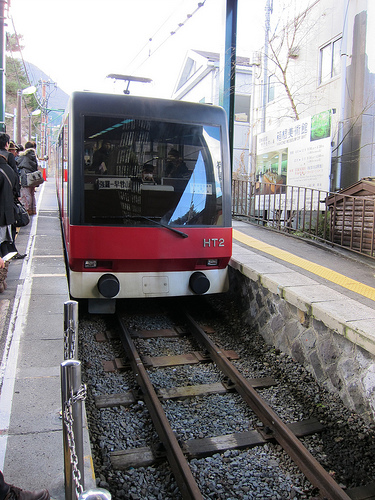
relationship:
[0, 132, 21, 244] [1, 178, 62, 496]
people standing on platform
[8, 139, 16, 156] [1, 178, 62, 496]
person standing on platform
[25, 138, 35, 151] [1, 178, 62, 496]
person standing on platform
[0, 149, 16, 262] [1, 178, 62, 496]
man standing on platform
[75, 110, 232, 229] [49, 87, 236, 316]
window on front of train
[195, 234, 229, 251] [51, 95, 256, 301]
written on front of train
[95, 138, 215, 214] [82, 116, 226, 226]
reflections on window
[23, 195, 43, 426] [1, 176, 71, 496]
lines are on platform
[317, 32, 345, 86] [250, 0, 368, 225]
window on building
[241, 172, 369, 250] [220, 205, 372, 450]
railing on platform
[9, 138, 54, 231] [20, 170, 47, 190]
lady holding big bag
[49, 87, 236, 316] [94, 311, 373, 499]
train on tracks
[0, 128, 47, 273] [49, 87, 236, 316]
people waiting train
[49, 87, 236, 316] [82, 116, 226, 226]
train has window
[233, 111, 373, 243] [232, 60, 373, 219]
sign on building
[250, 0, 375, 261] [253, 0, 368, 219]
building has wall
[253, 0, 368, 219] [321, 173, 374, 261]
wall has logs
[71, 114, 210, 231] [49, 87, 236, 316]
windshield on front of train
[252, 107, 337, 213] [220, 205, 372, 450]
sign next to platform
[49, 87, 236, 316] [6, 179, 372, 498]
train on platform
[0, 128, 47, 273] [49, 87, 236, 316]
people waiting for train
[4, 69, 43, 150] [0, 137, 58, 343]
light on platform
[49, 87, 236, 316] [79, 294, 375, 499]
train on railway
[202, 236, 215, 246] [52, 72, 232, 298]
letters on front of train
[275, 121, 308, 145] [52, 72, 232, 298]
letters on front of train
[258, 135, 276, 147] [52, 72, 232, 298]
letters on front of train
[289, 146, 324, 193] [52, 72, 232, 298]
letters on front of train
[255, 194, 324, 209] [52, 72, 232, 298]
letters on front of train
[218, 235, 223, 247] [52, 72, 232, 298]
number on front of train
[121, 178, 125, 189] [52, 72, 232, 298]
number on front of train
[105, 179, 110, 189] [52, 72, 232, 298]
number on front of train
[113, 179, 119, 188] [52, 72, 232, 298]
number on front of train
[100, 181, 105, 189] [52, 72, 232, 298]
number on front of train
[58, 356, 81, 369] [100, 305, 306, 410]
ring on railway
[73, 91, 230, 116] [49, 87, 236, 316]
head on train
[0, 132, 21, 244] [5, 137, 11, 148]
people has ear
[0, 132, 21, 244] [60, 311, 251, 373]
people along railway line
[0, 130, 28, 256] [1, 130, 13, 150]
man has head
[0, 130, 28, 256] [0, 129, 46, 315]
man along railway line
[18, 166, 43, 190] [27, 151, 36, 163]
back hanging on shoulder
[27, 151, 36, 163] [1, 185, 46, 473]
shoulder standing along railway line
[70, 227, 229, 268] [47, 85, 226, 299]
red part of head a train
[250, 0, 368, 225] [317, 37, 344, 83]
building has window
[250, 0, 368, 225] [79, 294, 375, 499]
building along railway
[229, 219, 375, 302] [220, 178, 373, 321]
line on platform